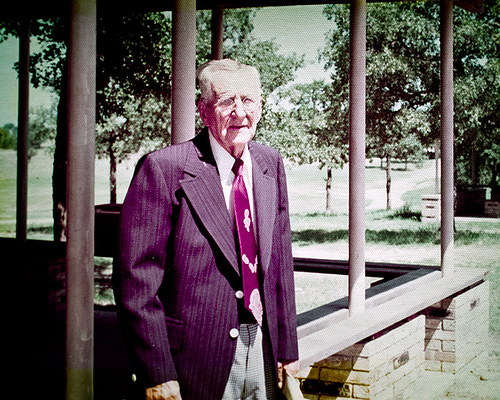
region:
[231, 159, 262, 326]
a purple neck tie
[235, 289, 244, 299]
a white plastic button on the jacket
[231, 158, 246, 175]
a standard neck tie knot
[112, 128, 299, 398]
a burgandy pin striped suit jacket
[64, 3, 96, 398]
a support column on a park gazebo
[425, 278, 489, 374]
a brick wall support of the gazebo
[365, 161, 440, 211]
a trail in the park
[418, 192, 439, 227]
a sign in the park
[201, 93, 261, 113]
wire rim eye glasses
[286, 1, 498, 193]
trees lining the park trail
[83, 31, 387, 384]
a man standing outside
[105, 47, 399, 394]
an old man standing outside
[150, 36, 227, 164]
a man wearing glasses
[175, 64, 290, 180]
an old man wearing glasses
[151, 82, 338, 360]
a man wearing a suit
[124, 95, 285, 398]
a man wearing a suit jacket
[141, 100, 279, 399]
a man wearing a jacket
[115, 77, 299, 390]
a man wearing a tie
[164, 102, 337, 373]
a man wearing a tie and jacket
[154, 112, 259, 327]
an old man wearing a tie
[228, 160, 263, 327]
A purple and white tie.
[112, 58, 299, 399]
An old man with a purple jacket and grey hair.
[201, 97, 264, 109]
Small round glasses on a man's face.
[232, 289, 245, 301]
Top white button on a purple jacket.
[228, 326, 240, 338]
Bottom white button on a purple jacket.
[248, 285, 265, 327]
White ice cream cone on the bottom of a purple tie.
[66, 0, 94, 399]
A grey and yellow pole to the left of a man.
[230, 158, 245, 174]
Purple knot at the top of a tie.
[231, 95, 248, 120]
A white nose on a man's face.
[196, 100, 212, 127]
An old man's right ear.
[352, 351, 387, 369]
white colored building brick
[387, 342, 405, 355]
white colored building brick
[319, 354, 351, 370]
white colored building brick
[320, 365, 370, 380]
white colored building brick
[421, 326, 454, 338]
white colored building brick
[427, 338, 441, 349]
white colored building brick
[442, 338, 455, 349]
white colored building brick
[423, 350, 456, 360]
white colored building brick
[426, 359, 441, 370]
white colored building brick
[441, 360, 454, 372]
white colored building brick